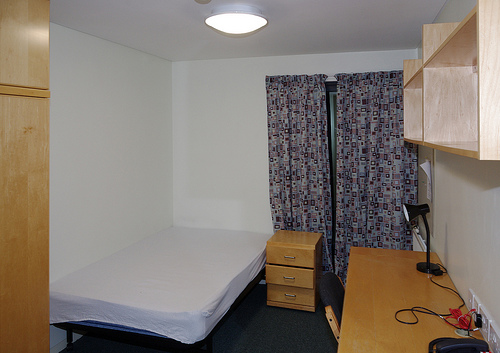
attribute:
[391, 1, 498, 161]
shelving — wooden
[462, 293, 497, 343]
outlet — white, electrical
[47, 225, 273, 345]
bed sheet — white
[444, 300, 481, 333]
cord — red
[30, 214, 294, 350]
bed — white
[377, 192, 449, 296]
lamp — black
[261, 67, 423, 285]
curtains — long, window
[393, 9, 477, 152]
cabinet — wooden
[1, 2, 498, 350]
bedroom — small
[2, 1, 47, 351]
cabinet — long, brown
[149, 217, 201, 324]
sheet — white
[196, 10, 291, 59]
light — round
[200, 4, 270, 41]
light — round, white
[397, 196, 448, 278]
lamp — black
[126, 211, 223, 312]
sheet — white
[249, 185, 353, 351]
drawer — small, brown